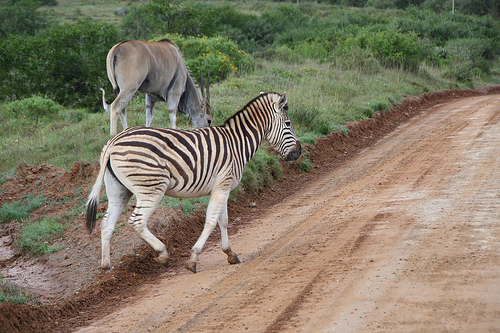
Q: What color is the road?
A: Brown.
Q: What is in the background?
A: Trees.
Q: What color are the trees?
A: Green.